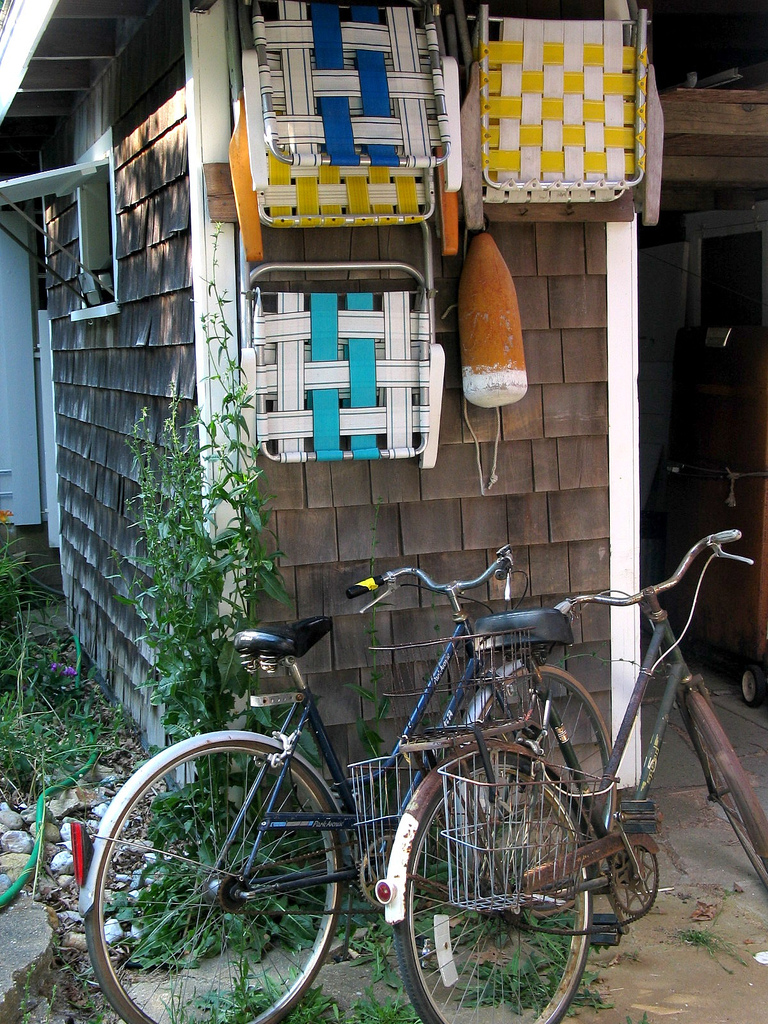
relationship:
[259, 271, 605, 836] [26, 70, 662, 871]
wall on building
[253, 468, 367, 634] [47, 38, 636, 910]
wall on building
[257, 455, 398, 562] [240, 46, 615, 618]
wall on side of building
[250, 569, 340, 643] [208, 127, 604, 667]
wall on side of building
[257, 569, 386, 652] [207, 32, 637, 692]
wall on side of building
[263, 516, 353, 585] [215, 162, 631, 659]
wall on building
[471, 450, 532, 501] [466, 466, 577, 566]
shingle on wall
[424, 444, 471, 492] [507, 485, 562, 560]
shingle on wall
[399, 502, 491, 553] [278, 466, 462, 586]
shingle on wall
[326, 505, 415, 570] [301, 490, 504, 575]
shingle on wall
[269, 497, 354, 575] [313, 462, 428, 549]
shingle on wall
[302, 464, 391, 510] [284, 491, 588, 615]
shingle on wall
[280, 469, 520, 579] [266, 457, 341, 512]
wall on shingle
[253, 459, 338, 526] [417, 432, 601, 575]
shingle on wall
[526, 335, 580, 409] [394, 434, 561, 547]
wall on shingle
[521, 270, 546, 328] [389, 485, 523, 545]
shingle on wall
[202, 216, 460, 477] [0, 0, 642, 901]
chair on building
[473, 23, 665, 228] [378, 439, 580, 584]
chair on house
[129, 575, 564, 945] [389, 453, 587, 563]
bike on house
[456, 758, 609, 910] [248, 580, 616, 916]
basket on bike